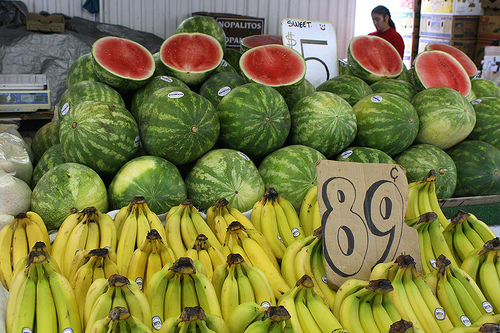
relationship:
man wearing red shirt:
[369, 0, 407, 57] [367, 31, 404, 60]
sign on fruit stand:
[276, 10, 343, 97] [5, 25, 497, 328]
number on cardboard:
[321, 175, 368, 280] [313, 157, 425, 289]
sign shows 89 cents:
[319, 155, 424, 292] [319, 174, 405, 279]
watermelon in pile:
[28, 15, 500, 231] [19, 19, 498, 216]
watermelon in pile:
[349, 90, 419, 156] [19, 19, 498, 216]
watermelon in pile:
[317, 72, 364, 104] [19, 19, 498, 216]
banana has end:
[131, 271, 213, 318] [161, 255, 206, 279]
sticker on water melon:
[203, 79, 239, 108] [204, 67, 296, 161]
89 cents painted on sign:
[322, 162, 401, 274] [319, 155, 424, 292]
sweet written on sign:
[285, 20, 313, 27] [279, 18, 335, 80]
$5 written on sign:
[281, 29, 329, 83] [279, 18, 335, 80]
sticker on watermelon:
[165, 90, 185, 100] [135, 86, 221, 164]